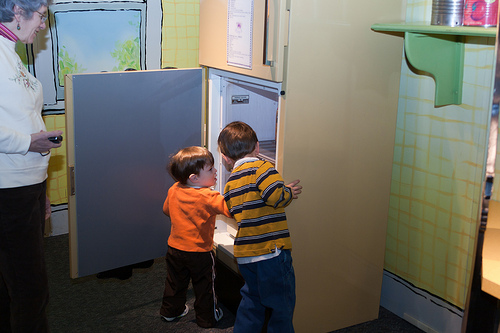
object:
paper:
[224, 0, 255, 71]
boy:
[215, 118, 307, 332]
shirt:
[160, 180, 233, 254]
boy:
[159, 143, 235, 329]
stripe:
[207, 250, 219, 321]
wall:
[379, 1, 500, 332]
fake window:
[52, 8, 144, 87]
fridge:
[61, 0, 409, 333]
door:
[62, 67, 213, 278]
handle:
[259, 1, 271, 67]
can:
[459, 0, 499, 29]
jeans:
[230, 248, 298, 332]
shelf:
[369, 20, 495, 39]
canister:
[429, 0, 466, 28]